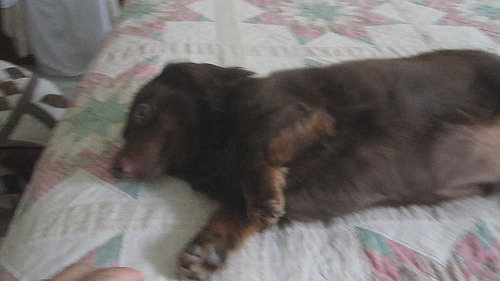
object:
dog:
[111, 48, 500, 281]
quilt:
[0, 0, 500, 281]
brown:
[330, 79, 374, 112]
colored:
[349, 223, 452, 281]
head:
[111, 60, 253, 185]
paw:
[176, 244, 226, 279]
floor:
[0, 58, 80, 236]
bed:
[0, 1, 500, 281]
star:
[246, 0, 404, 47]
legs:
[188, 201, 264, 248]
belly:
[344, 128, 500, 210]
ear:
[170, 62, 260, 100]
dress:
[23, 0, 118, 79]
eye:
[134, 101, 150, 121]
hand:
[43, 246, 147, 281]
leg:
[242, 117, 301, 204]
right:
[176, 205, 248, 281]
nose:
[103, 156, 125, 176]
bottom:
[181, 248, 231, 280]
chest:
[193, 146, 261, 203]